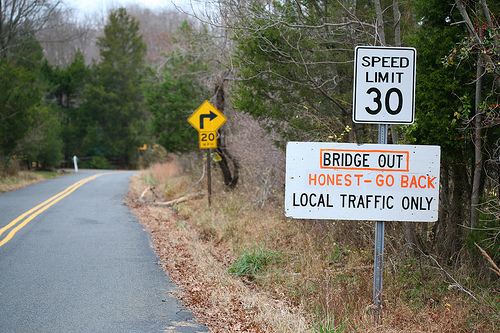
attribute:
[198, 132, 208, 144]
number — black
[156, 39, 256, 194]
tree — in the picture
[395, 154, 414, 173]
letter — black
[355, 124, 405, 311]
pole — metal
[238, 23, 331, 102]
leaves — green 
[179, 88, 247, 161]
sign — Yellow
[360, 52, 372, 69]
letter — black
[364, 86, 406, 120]
number — black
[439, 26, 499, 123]
leaves — different colors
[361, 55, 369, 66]
letter — black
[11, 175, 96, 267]
stripes — in the picture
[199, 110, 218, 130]
arrow — pointing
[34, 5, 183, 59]
tree — Leafless, grey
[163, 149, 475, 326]
bushes — bushy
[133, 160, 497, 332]
grass — long, dried out, in the picture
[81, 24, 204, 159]
trees — evergreen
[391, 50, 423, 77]
letter — black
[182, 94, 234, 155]
yellow sign — yellow 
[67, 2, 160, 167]
tree — in the picture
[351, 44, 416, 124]
road sign — White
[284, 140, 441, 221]
road sign — White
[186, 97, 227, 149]
road sign — White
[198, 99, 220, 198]
post — in the picture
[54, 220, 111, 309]
road — tarmacked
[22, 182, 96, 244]
road — small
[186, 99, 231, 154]
yellow — in the picture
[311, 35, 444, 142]
sign — speed limit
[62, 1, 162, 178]
pin tree — Tall, green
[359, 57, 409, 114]
writting — black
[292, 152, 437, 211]
writting — black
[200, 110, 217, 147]
writting — black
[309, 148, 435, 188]
writting — orange 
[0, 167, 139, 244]
lines — Yellow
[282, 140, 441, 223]
sign — warning